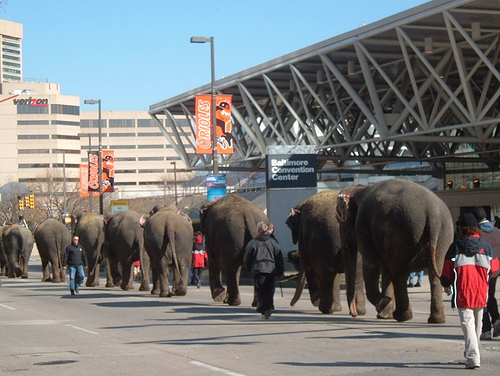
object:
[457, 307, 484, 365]
beige pants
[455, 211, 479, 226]
black hat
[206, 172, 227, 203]
blue sign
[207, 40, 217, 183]
pole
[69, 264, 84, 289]
jeans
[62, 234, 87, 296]
man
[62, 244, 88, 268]
jacket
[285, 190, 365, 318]
elephant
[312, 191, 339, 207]
dirt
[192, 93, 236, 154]
sign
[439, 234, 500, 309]
jacket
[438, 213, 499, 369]
man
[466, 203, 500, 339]
man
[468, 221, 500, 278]
jacket